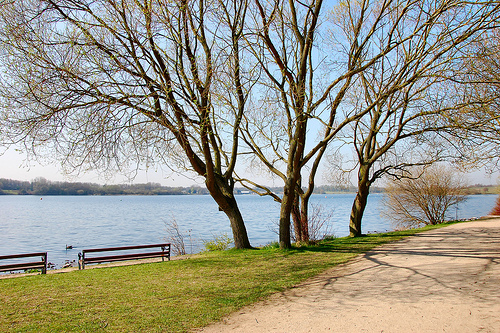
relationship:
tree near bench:
[1, 1, 281, 260] [76, 240, 172, 271]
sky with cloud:
[6, 2, 476, 187] [8, 122, 476, 189]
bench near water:
[81, 244, 216, 278] [94, 163, 198, 230]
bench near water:
[0, 251, 50, 278] [2, 189, 491, 228]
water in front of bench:
[0, 191, 497, 276] [0, 246, 55, 288]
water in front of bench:
[0, 191, 497, 276] [77, 238, 180, 275]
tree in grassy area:
[1, 1, 255, 250] [5, 223, 424, 331]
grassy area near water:
[5, 223, 424, 331] [0, 188, 493, 261]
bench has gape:
[75, 241, 171, 270] [77, 242, 170, 259]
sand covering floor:
[375, 275, 467, 327] [185, 213, 498, 332]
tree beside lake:
[1, 1, 255, 250] [1, 183, 490, 271]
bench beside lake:
[75, 241, 171, 270] [2, 193, 499, 274]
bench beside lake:
[0, 251, 50, 278] [2, 193, 499, 274]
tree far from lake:
[1, 1, 255, 250] [1, 191, 498, 245]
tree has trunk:
[1, 1, 281, 260] [190, 167, 267, 256]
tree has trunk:
[1, 1, 255, 250] [272, 199, 296, 249]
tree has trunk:
[325, 0, 499, 240] [345, 161, 370, 236]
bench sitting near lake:
[75, 241, 171, 270] [3, 171, 398, 269]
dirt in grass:
[0, 236, 392, 328] [0, 218, 467, 331]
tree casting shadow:
[1, 1, 255, 250] [307, 235, 498, 287]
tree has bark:
[1, 1, 281, 260] [222, 197, 224, 202]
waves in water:
[3, 193, 499, 272] [1, 197, 488, 258]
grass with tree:
[0, 218, 467, 331] [1, 1, 255, 250]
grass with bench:
[0, 218, 467, 331] [0, 252, 45, 276]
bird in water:
[62, 241, 76, 253] [0, 191, 497, 276]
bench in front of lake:
[0, 251, 49, 278] [1, 191, 500, 275]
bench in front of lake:
[75, 241, 171, 270] [1, 191, 500, 275]